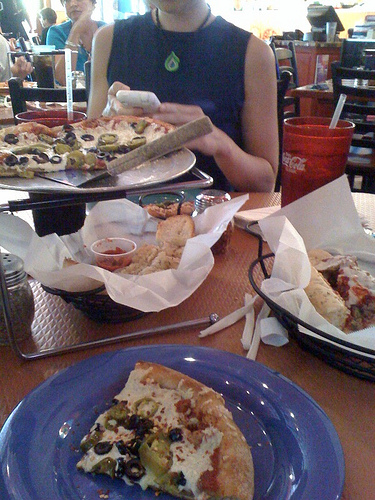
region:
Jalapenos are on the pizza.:
[97, 130, 118, 142]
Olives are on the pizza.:
[119, 457, 145, 478]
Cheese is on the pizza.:
[78, 371, 218, 488]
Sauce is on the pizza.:
[97, 376, 222, 499]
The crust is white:
[131, 354, 257, 498]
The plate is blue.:
[15, 360, 353, 498]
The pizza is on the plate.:
[29, 366, 305, 498]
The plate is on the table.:
[0, 353, 367, 496]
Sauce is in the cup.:
[93, 236, 133, 263]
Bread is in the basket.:
[26, 221, 234, 296]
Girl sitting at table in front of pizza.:
[85, 1, 282, 194]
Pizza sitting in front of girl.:
[3, 113, 197, 194]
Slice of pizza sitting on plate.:
[74, 354, 265, 498]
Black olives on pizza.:
[94, 433, 142, 476]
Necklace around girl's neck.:
[149, 2, 213, 72]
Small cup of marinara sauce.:
[87, 233, 138, 268]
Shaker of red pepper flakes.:
[194, 190, 234, 256]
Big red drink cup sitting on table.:
[277, 111, 354, 201]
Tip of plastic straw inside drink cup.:
[328, 92, 350, 126]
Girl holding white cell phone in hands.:
[113, 85, 166, 117]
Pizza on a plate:
[1, 342, 347, 498]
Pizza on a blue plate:
[2, 340, 349, 497]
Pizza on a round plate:
[0, 339, 347, 499]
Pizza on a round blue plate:
[2, 338, 348, 498]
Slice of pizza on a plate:
[1, 340, 348, 499]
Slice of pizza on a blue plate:
[2, 340, 348, 499]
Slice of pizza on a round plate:
[1, 339, 347, 497]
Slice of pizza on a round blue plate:
[0, 339, 345, 494]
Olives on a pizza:
[83, 390, 190, 484]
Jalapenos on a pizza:
[80, 392, 180, 491]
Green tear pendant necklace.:
[151, 1, 214, 78]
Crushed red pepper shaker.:
[194, 190, 236, 256]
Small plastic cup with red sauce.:
[92, 228, 135, 264]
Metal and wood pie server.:
[40, 114, 225, 187]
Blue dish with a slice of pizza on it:
[1, 341, 345, 496]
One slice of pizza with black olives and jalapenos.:
[73, 356, 251, 497]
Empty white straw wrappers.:
[197, 287, 273, 363]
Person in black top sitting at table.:
[85, 4, 282, 192]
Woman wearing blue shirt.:
[47, 0, 115, 75]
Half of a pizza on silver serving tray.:
[0, 113, 200, 189]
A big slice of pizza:
[74, 357, 256, 498]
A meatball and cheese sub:
[306, 219, 368, 335]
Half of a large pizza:
[6, 108, 184, 186]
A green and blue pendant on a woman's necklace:
[159, 52, 199, 80]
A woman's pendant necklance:
[105, 8, 242, 96]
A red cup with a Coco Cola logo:
[275, 110, 366, 246]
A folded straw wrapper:
[218, 290, 292, 362]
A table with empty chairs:
[272, 36, 374, 119]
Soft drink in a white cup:
[24, 43, 65, 91]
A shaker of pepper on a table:
[196, 193, 233, 255]